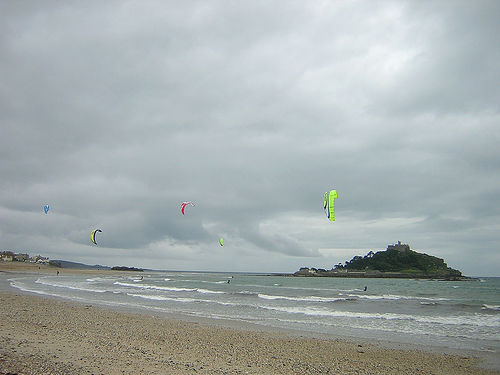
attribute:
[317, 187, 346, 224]
kite — yellow, large, green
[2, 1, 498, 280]
sky — blue, cloudy, overcast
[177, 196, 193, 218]
kite — red, flying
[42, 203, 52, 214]
kite — blue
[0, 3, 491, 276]
clouds — white, grey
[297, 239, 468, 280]
mountains — brown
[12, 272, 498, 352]
water — grey